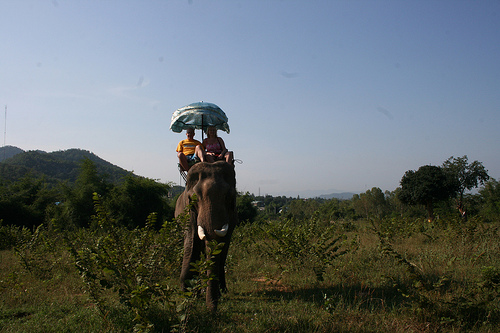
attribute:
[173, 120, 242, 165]
couple — riding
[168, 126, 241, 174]
people — riding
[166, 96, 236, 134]
parasol — blue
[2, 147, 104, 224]
hills — green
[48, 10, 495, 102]
sky — blue, clear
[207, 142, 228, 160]
tank top — pink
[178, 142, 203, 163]
shirt — orange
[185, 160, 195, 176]
shorts — blue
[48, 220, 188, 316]
bushes — green, small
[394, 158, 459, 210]
tree — green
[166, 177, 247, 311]
elephant — grey, standing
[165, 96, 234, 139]
umbrella — blue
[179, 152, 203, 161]
shirt — yellow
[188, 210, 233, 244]
tusks — white